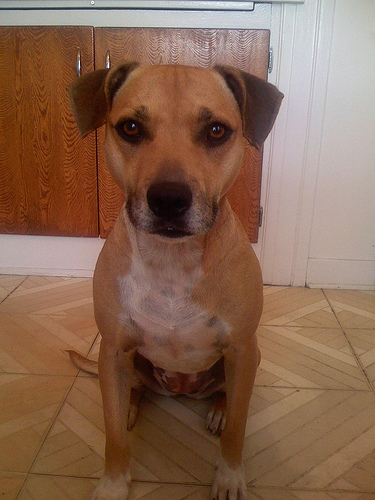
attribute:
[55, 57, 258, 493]
dog — brown, sitting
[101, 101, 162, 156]
eye — brown, open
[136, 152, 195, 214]
nose — black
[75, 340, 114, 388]
tail — brown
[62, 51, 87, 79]
handle — silver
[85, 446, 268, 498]
paws — white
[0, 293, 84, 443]
floor — tile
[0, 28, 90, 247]
cupboard — brown, wooden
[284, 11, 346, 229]
wall — white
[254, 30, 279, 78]
hinge — metal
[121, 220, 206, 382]
chest — white